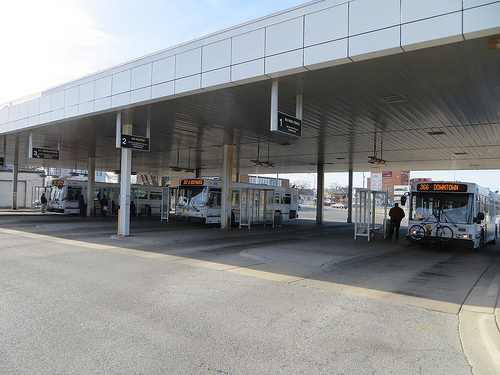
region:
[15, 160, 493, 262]
Three city buses parked in a row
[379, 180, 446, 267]
Man standing beside a city bus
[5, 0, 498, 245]
City bus terminal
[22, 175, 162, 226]
People standing around a bus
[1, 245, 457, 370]
Asphalt and concrete road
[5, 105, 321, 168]
Signs at the bus terminal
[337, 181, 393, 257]
Booth for waiting at a bus terminal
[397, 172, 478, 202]
Light up sign on the front of a bus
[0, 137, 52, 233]
Garage beside bus terminal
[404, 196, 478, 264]
Bicycle on the front of a bus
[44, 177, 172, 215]
large white bus at stop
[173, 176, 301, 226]
large white bus at stop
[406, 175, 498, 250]
large white bus at stop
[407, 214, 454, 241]
bike attached to front of bus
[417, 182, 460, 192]
yellow lettering at top of bus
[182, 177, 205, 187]
yellow lettering at top of bus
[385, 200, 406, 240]
person standing next to bus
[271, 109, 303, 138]
black sign hanging above road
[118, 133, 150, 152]
black sign hanging above road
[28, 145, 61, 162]
black sign hanging above road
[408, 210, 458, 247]
a bicycle on the front of a bus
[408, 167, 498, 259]
a white bus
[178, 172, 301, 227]
a white bus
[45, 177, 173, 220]
a white bus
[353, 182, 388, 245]
a bus stop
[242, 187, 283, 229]
a bus stop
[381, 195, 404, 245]
a person waiting outside the bus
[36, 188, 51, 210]
a person waiting outside the bus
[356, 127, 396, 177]
a pair of hanging lights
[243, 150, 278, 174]
a pair of hanging lights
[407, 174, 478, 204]
this is orange font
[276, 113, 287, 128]
this is the number 1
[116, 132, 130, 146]
the white number 2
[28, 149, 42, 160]
this is the number 3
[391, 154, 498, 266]
this is a bus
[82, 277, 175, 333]
this is the concrete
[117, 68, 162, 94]
these are white tiles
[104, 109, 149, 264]
this is a pillar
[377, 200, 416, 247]
this is a person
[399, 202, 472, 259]
this is a bicycle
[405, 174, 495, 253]
a white public service bus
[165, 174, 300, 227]
a white public service bus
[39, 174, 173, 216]
a white public service bus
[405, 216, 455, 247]
a rack mounted bicycle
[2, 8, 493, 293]
a bus station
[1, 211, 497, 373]
a grey paved roadway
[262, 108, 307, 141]
an passenger informational sign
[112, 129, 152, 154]
an passenger informational sign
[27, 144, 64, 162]
an passenger informational sign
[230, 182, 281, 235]
a passenger shelter